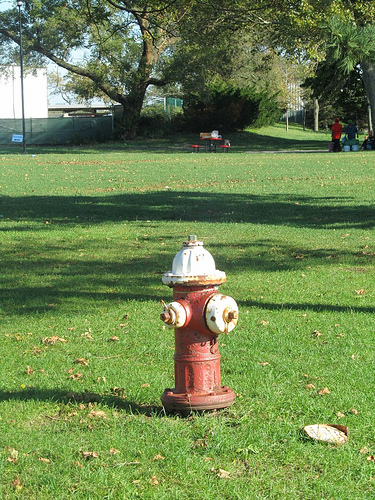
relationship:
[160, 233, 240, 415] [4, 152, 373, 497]
hydrant in grass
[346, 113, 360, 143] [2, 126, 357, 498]
person standing in grass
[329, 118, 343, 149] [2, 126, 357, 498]
person standing in grass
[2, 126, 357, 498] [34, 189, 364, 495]
grass with leaves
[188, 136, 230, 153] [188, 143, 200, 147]
picnic table with seat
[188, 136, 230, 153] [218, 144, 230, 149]
picnic table with seat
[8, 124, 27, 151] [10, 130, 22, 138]
sign with letters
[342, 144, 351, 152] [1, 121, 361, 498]
bucket sitting on ground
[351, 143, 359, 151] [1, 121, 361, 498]
bucket sitting on ground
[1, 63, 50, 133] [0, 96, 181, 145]
building standing behind fence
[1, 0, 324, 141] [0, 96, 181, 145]
tree growing next to fence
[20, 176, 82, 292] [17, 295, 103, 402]
shadows in grass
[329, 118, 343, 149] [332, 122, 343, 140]
person wearing shirt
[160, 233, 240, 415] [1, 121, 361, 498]
hydrant on ground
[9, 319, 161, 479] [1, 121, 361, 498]
leaves on ground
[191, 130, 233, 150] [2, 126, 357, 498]
bench in grass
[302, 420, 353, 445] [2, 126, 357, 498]
paper on grass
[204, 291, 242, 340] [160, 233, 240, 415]
plug on hydrant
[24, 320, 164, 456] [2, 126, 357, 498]
leaves on grass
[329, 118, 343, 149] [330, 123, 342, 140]
person in jacket